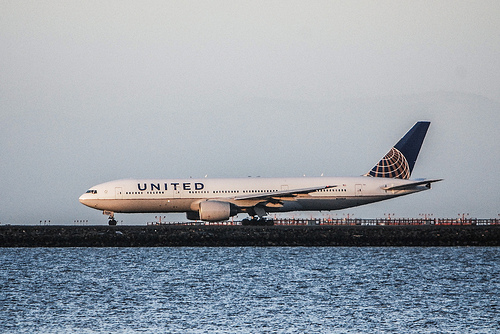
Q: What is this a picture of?
A: A plane.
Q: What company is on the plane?
A: United.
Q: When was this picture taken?
A: Daytime.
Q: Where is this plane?
A: On the ground.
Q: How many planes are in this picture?
A: One.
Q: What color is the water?
A: Blue.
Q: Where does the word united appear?
A: On the plane.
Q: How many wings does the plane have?
A: Two.